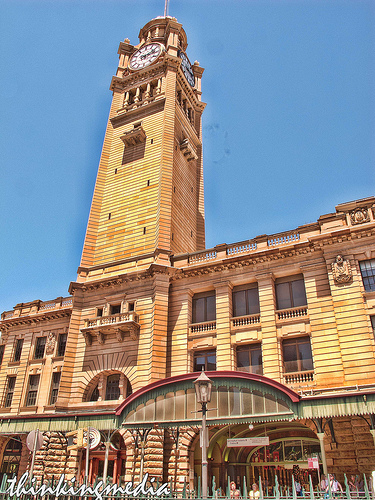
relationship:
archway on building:
[108, 360, 304, 431] [0, 2, 374, 496]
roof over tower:
[136, 8, 200, 49] [52, 6, 215, 411]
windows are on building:
[183, 259, 326, 399] [0, 2, 374, 496]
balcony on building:
[75, 303, 153, 349] [0, 2, 374, 496]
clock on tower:
[125, 34, 167, 75] [52, 6, 215, 411]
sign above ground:
[222, 424, 285, 451] [0, 477, 370, 498]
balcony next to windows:
[75, 303, 153, 349] [183, 259, 326, 399]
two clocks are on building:
[121, 41, 209, 90] [0, 2, 374, 496]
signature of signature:
[7, 474, 179, 499] [6, 472, 172, 500]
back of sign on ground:
[26, 424, 56, 455] [0, 477, 370, 498]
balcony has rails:
[75, 303, 153, 349] [120, 313, 136, 325]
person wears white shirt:
[240, 475, 265, 498] [249, 488, 268, 498]